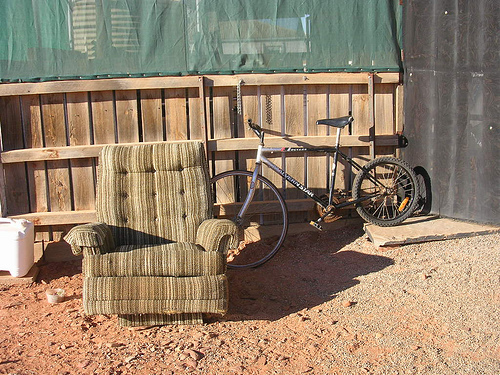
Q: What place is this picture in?
A: It is at the yard.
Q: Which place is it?
A: It is a yard.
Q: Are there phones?
A: No, there are no phones.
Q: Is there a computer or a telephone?
A: No, there are no phones or computers.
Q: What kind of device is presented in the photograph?
A: The device is a screen.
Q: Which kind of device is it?
A: The device is a screen.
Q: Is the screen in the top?
A: Yes, the screen is in the top of the image.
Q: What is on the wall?
A: The screen is on the wall.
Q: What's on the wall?
A: The screen is on the wall.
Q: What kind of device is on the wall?
A: The device is a screen.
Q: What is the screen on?
A: The screen is on the wall.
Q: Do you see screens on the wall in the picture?
A: Yes, there is a screen on the wall.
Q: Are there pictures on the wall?
A: No, there is a screen on the wall.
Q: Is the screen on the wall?
A: Yes, the screen is on the wall.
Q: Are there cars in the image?
A: No, there are no cars.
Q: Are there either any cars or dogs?
A: No, there are no cars or dogs.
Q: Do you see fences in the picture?
A: Yes, there is a fence.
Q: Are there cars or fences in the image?
A: Yes, there is a fence.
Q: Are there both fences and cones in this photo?
A: No, there is a fence but no cones.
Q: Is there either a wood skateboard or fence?
A: Yes, there is a wood fence.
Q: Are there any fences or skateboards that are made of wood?
A: Yes, the fence is made of wood.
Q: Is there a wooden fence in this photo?
A: Yes, there is a wood fence.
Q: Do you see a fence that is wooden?
A: Yes, there is a fence that is wooden.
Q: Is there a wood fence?
A: Yes, there is a fence that is made of wood.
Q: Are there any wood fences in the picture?
A: Yes, there is a fence that is made of wood.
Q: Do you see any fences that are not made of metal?
A: Yes, there is a fence that is made of wood.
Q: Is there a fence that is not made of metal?
A: Yes, there is a fence that is made of wood.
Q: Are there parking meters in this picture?
A: No, there are no parking meters.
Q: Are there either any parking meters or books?
A: No, there are no parking meters or books.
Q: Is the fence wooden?
A: Yes, the fence is wooden.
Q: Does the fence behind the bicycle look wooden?
A: Yes, the fence is wooden.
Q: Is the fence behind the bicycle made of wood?
A: Yes, the fence is made of wood.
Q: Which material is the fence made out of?
A: The fence is made of wood.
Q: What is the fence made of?
A: The fence is made of wood.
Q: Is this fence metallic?
A: No, the fence is wooden.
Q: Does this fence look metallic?
A: No, the fence is wooden.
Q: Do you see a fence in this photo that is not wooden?
A: No, there is a fence but it is wooden.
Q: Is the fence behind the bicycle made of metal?
A: No, the fence is made of wood.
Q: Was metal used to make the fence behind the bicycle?
A: No, the fence is made of wood.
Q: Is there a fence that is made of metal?
A: No, there is a fence but it is made of wood.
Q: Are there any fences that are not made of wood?
A: No, there is a fence but it is made of wood.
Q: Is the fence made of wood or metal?
A: The fence is made of wood.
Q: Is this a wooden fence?
A: Yes, this is a wooden fence.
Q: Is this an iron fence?
A: No, this is a wooden fence.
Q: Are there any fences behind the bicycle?
A: Yes, there is a fence behind the bicycle.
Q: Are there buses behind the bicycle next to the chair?
A: No, there is a fence behind the bicycle.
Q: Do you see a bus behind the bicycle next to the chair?
A: No, there is a fence behind the bicycle.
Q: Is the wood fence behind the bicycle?
A: Yes, the fence is behind the bicycle.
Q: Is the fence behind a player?
A: No, the fence is behind the bicycle.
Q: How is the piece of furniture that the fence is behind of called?
A: The piece of furniture is a chair.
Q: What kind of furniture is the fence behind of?
A: The fence is behind the chair.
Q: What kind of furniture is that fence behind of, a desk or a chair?
A: The fence is behind a chair.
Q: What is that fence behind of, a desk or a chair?
A: The fence is behind a chair.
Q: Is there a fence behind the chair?
A: Yes, there is a fence behind the chair.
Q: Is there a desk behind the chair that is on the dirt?
A: No, there is a fence behind the chair.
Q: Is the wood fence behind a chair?
A: Yes, the fence is behind a chair.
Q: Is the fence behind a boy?
A: No, the fence is behind a chair.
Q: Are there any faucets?
A: No, there are no faucets.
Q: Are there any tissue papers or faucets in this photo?
A: No, there are no faucets or tissue papers.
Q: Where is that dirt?
A: The dirt is in the yard.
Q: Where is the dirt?
A: The dirt is in the yard.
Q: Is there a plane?
A: No, there are no airplanes.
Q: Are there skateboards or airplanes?
A: No, there are no airplanes or skateboards.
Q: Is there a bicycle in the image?
A: Yes, there is a bicycle.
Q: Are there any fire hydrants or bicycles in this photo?
A: Yes, there is a bicycle.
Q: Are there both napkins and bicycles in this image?
A: No, there is a bicycle but no napkins.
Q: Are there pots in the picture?
A: No, there are no pots.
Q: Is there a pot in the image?
A: No, there are no pots.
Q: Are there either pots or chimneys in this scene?
A: No, there are no pots or chimneys.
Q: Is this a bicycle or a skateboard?
A: This is a bicycle.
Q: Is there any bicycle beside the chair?
A: Yes, there is a bicycle beside the chair.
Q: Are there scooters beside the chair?
A: No, there is a bicycle beside the chair.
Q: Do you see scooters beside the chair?
A: No, there is a bicycle beside the chair.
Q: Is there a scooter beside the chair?
A: No, there is a bicycle beside the chair.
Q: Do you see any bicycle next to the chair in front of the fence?
A: Yes, there is a bicycle next to the chair.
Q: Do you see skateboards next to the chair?
A: No, there is a bicycle next to the chair.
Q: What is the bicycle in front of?
A: The bicycle is in front of the fence.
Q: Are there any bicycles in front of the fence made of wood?
A: Yes, there is a bicycle in front of the fence.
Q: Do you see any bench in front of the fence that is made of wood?
A: No, there is a bicycle in front of the fence.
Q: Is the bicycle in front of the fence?
A: Yes, the bicycle is in front of the fence.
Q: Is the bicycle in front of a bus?
A: No, the bicycle is in front of the fence.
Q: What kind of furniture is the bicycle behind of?
A: The bicycle is behind the chair.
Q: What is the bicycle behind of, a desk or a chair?
A: The bicycle is behind a chair.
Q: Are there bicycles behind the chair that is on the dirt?
A: Yes, there is a bicycle behind the chair.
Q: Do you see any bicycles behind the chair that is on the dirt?
A: Yes, there is a bicycle behind the chair.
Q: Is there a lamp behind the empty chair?
A: No, there is a bicycle behind the chair.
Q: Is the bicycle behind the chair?
A: Yes, the bicycle is behind the chair.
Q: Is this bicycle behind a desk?
A: No, the bicycle is behind the chair.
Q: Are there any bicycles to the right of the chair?
A: Yes, there is a bicycle to the right of the chair.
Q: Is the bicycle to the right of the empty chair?
A: Yes, the bicycle is to the right of the chair.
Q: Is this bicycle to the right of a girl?
A: No, the bicycle is to the right of the chair.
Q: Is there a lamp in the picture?
A: No, there are no lamps.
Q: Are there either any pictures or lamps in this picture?
A: No, there are no lamps or pictures.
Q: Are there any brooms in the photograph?
A: No, there are no brooms.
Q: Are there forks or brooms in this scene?
A: No, there are no brooms or forks.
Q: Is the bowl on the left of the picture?
A: Yes, the bowl is on the left of the image.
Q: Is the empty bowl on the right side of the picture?
A: No, the bowl is on the left of the image.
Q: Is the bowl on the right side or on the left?
A: The bowl is on the left of the image.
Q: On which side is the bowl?
A: The bowl is on the left of the image.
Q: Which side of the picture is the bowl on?
A: The bowl is on the left of the image.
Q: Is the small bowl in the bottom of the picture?
A: Yes, the bowl is in the bottom of the image.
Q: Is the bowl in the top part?
A: No, the bowl is in the bottom of the image.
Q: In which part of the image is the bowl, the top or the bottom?
A: The bowl is in the bottom of the image.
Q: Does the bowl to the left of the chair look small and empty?
A: Yes, the bowl is small and empty.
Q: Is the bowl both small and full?
A: No, the bowl is small but empty.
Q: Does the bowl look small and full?
A: No, the bowl is small but empty.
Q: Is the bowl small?
A: Yes, the bowl is small.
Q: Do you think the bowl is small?
A: Yes, the bowl is small.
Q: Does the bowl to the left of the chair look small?
A: Yes, the bowl is small.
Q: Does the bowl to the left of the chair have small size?
A: Yes, the bowl is small.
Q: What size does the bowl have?
A: The bowl has small size.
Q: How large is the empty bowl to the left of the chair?
A: The bowl is small.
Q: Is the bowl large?
A: No, the bowl is small.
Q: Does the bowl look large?
A: No, the bowl is small.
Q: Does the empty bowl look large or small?
A: The bowl is small.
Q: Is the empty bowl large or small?
A: The bowl is small.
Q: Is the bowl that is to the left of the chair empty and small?
A: Yes, the bowl is empty and small.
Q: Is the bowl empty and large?
A: No, the bowl is empty but small.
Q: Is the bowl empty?
A: Yes, the bowl is empty.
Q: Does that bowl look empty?
A: Yes, the bowl is empty.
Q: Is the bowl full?
A: No, the bowl is empty.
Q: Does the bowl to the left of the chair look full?
A: No, the bowl is empty.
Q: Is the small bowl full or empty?
A: The bowl is empty.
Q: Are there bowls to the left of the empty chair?
A: Yes, there is a bowl to the left of the chair.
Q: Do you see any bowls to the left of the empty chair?
A: Yes, there is a bowl to the left of the chair.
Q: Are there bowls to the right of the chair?
A: No, the bowl is to the left of the chair.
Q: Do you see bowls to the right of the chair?
A: No, the bowl is to the left of the chair.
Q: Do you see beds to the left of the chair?
A: No, there is a bowl to the left of the chair.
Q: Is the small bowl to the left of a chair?
A: Yes, the bowl is to the left of a chair.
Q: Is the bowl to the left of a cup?
A: No, the bowl is to the left of a chair.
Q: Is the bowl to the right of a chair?
A: No, the bowl is to the left of a chair.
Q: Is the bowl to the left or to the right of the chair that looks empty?
A: The bowl is to the left of the chair.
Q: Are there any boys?
A: No, there are no boys.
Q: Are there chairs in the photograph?
A: Yes, there is a chair.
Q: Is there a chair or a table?
A: Yes, there is a chair.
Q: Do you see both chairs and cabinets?
A: No, there is a chair but no cabinets.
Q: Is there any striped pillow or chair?
A: Yes, there is a striped chair.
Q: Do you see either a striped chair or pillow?
A: Yes, there is a striped chair.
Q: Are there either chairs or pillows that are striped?
A: Yes, the chair is striped.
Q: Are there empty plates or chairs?
A: Yes, there is an empty chair.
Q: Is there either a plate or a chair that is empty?
A: Yes, the chair is empty.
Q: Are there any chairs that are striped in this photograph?
A: Yes, there is a striped chair.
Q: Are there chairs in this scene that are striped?
A: Yes, there is a chair that is striped.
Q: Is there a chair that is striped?
A: Yes, there is a chair that is striped.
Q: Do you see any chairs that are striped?
A: Yes, there is a chair that is striped.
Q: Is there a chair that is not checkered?
A: Yes, there is a striped chair.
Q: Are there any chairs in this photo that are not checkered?
A: Yes, there is a striped chair.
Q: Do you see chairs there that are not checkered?
A: Yes, there is a striped chair.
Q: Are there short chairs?
A: Yes, there is a short chair.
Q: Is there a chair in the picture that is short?
A: Yes, there is a chair that is short.